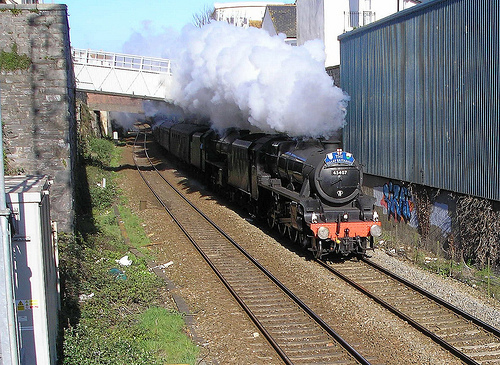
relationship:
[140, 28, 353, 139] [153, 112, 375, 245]
steam coming from train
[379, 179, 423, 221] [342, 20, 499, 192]
graffiti on metal wall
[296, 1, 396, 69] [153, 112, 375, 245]
white house next to train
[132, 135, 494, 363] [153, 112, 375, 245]
train tracks under train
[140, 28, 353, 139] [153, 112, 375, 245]
smoke from train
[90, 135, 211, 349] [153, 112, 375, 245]
ground next to train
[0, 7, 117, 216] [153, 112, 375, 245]
fence next to train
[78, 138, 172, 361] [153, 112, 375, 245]
grass next to train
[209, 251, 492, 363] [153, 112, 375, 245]
tracks in front of train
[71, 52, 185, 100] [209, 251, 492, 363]
bridge over tracks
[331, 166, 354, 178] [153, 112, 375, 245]
numbers on train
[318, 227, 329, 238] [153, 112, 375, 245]
light on front of train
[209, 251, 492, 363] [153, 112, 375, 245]
tracks next to train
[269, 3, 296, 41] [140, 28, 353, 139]
roof above smoke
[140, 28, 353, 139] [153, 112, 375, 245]
white smoke on top of train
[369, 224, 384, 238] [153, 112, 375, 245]
light on train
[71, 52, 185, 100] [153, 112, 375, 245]
overpass above train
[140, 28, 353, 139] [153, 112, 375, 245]
smoke billowing from train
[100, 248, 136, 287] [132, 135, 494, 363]
trash along train track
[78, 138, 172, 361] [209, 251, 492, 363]
grass along tracks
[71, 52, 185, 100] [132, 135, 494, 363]
bridge over train tracks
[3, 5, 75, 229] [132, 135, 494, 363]
stone wall near train tracks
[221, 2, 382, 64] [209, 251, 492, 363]
building next to tracks